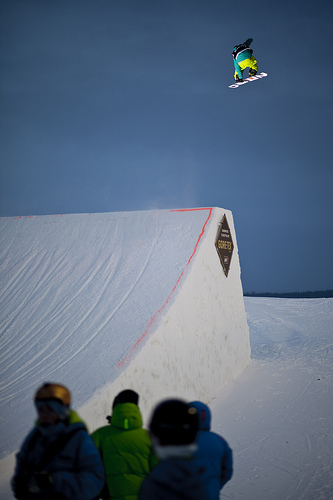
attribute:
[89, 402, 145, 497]
jacket — green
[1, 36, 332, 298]
sky — clear, blue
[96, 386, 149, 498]
coat — lime, green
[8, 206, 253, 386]
snow ramp — tall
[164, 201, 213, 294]
marking — pink